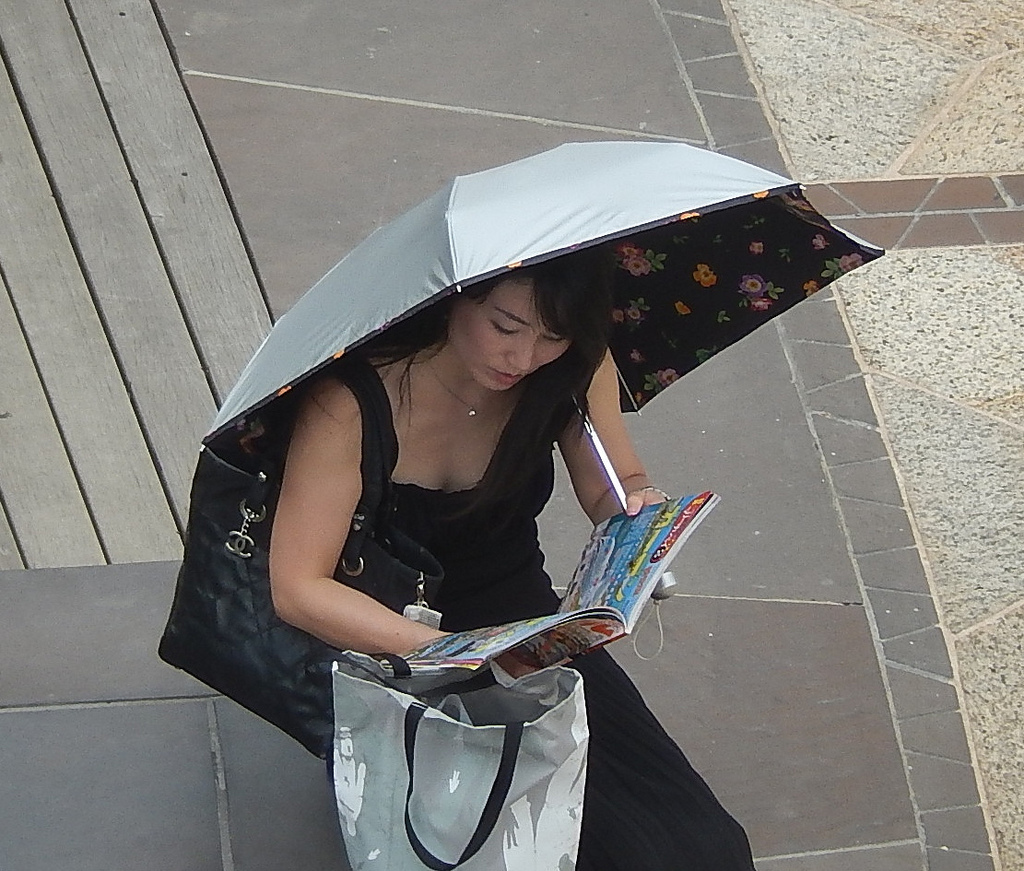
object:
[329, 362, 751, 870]
dress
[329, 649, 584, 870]
bag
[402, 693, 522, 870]
handles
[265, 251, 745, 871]
woman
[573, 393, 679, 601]
pole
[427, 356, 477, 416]
necklace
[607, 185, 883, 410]
design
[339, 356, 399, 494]
strap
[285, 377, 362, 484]
shoulder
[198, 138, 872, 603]
umbrella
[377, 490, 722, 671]
magazine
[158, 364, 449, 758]
bag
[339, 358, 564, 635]
shirt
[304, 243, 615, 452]
hair